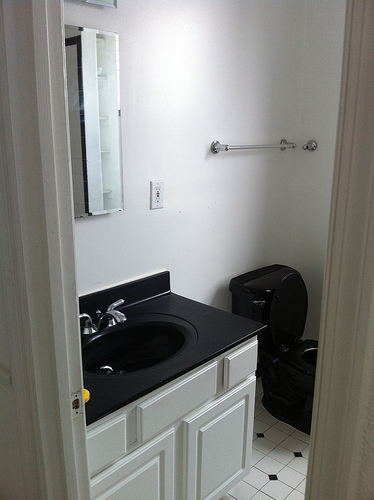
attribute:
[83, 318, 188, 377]
bathroom sink — black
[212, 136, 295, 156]
rack — silver